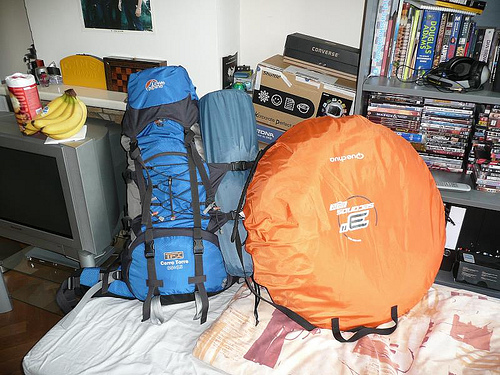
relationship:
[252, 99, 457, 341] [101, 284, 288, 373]
orange bag on bed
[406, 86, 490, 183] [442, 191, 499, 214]
dvds on shelf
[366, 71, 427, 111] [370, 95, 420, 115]
shelf with dvd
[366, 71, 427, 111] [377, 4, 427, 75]
shelf with books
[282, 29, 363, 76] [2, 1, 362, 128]
shoe box on wall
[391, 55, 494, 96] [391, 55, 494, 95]
headphones has headphones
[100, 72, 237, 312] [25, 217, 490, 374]
blue backpack on bed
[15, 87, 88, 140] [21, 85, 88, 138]
bananas have bunch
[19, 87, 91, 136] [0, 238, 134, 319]
bananas on table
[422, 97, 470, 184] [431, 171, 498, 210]
dvd stack on shelf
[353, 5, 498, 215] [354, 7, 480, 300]
dvds on shelf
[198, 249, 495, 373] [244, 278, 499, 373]
pillow case with design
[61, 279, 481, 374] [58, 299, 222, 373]
bed covered in sheet